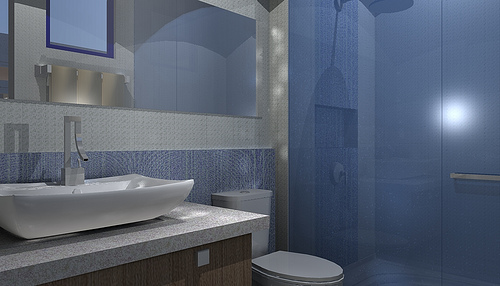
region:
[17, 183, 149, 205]
the sink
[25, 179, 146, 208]
the sink is white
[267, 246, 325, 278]
the toilet seat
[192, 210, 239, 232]
the counter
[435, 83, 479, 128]
light on the wall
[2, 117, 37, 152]
shadow on the wall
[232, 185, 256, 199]
button on the toilet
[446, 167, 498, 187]
handle on the door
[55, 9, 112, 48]
a window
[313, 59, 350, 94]
a shadow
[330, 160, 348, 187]
shower handle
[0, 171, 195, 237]
white raised sink bowl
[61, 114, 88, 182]
modern metal faucet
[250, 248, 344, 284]
white toliet bowl lid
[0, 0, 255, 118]
bathroom mirror mounted on wall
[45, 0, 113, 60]
window reflected in the mirror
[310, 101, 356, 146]
recessed shelf in the shower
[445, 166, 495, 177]
metal towel bar on glass door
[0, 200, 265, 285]
stone bathroom counter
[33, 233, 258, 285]
wooden bathroom sink cabinet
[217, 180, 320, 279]
toilet in the bathroom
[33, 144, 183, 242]
sink in the bathroom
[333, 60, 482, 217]
bathroom with blue walls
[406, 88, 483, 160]
glare on the wall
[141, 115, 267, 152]
white stripe on the wall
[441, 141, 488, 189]
silver bar in shower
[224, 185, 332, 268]
toilet next to sink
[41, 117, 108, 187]
chrome faucet on sink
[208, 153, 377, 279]
toilet next to shower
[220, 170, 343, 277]
toilet between shower and sink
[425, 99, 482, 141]
light on the wall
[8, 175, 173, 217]
the sink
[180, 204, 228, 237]
the counter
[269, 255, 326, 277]
the toilet seat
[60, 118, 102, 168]
a faucet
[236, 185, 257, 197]
button on top of the toilet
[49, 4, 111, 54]
the window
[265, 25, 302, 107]
a shadow on the wall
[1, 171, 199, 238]
white sink on top of vanity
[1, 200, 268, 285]
corian counter under sink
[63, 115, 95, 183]
chrome faucet on sink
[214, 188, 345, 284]
clean white toilet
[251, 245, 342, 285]
toilet seat lid is down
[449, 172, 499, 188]
handle on shower door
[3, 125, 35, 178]
shadow behind faucet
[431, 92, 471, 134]
reflection on shower door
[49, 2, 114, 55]
window above vanity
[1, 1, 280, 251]
wall behind white toilet